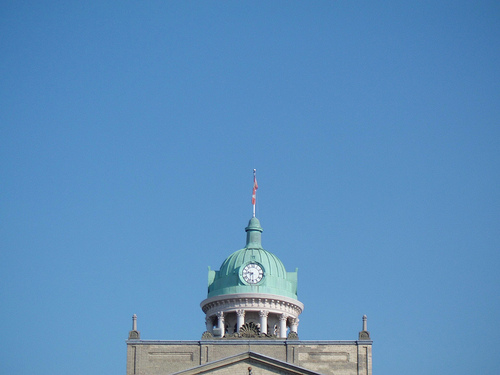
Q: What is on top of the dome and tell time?
A: Clock.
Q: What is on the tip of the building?
A: Flag.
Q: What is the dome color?
A: Blue.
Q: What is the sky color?
A: Blue.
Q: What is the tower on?
A: Building.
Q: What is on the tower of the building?
A: Clock.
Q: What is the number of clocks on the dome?
A: One.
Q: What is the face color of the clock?
A: White.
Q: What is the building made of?
A: Concrete.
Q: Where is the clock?
A: On the building.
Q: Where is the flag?
A: ON the building.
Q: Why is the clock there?
A: To tell time.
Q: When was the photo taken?
A: Day time.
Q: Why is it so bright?
A: Sunny.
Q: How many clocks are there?
A: One.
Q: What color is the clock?
A: White.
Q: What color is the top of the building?
A: Green.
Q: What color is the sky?
A: Blue.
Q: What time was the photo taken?
A: Morning.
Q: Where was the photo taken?
A: At a church.